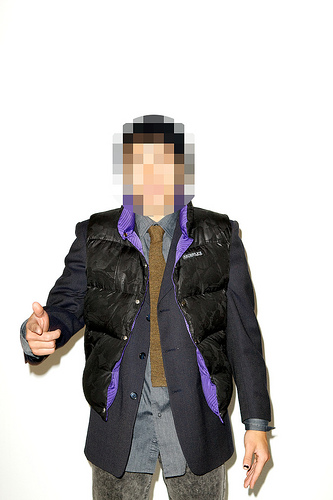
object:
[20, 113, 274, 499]
man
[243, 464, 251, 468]
nailpolish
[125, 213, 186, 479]
shirt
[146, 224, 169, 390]
tie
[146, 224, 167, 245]
knot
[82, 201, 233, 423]
vest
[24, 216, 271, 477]
jacket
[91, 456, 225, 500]
jean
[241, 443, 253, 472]
thumb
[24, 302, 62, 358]
hand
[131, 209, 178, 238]
collar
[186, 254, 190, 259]
letters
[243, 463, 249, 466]
nail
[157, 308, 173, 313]
button hole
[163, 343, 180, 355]
button hole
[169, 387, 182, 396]
button hole